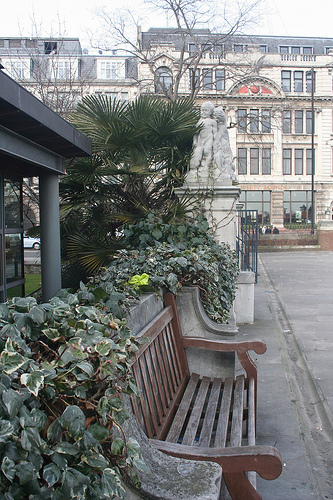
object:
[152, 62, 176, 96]
window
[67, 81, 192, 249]
plant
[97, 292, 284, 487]
bench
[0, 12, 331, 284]
building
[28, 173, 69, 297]
pillar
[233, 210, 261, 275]
fencing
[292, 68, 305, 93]
windows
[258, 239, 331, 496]
sidewalk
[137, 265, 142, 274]
leaves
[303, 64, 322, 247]
pole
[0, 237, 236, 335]
planter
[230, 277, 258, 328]
wall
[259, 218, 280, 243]
people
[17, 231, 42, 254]
car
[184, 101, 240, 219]
statue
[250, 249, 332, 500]
street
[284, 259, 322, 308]
patch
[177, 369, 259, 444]
seat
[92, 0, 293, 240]
tree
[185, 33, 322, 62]
words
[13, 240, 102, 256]
street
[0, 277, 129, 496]
bushes